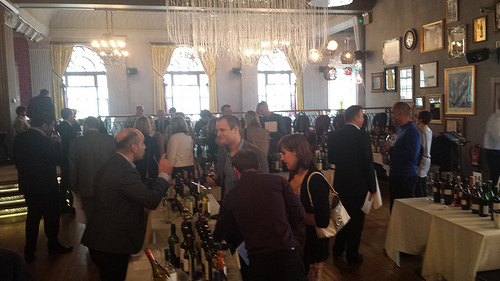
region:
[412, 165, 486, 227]
wine bottles on table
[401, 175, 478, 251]
wine bottles on table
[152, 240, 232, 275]
wine bottles on table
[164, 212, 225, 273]
wine bottles on table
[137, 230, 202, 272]
wine bottles on table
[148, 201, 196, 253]
wine bottles on table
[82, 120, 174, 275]
Man with a balding head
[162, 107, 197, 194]
Woman wearing a white jacket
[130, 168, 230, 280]
Table full of wine bottles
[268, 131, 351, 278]
Woman with purse on shoulder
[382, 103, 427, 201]
Man wearing a blue shirt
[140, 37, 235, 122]
Window with yellow drapes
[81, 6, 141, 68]
Light hanging from ceiling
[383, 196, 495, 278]
White table cloth on table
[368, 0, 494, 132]
Group of pictures on a wall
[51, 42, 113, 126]
a big light window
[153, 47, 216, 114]
a big light window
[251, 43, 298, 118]
a big light window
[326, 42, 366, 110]
a big light window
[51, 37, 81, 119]
a long golden curtain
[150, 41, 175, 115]
a long golden curtain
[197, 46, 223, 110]
a long golden curtain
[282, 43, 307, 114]
a long golden curtain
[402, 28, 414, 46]
a picture on the wall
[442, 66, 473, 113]
a picture on the wall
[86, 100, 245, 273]
a guy talking to another person across the table with wine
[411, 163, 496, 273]
a table with bottles of wine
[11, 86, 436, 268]
a people standing chatting and tasting wine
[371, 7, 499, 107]
wall with picture frames, clock and mirror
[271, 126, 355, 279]
a woman with a shoulder bag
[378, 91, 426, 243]
a guy wearing blue shirt holding a glass of wine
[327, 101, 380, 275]
a man wearing a black suit with a piece of paper on his hand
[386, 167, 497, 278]
a table with white table cloth with bottles of wine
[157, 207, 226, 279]
a bottles of wine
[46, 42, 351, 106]
large and bright windows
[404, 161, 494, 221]
wines on top of table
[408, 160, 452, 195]
wines on top of table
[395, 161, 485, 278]
wines on top of table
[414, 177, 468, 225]
wines on top of table